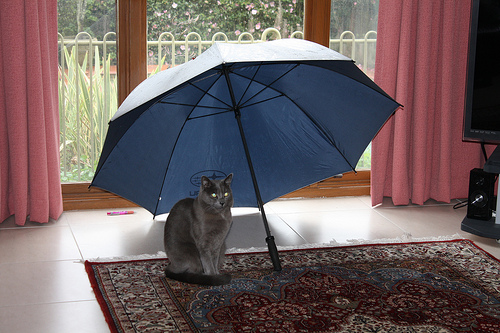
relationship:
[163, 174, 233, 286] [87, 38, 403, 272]
cat under umbrella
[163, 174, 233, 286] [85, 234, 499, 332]
cat on rug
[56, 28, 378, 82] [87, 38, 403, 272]
fence behind umbrella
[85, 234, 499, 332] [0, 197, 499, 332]
rug on floor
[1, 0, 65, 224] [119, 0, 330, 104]
curtains near door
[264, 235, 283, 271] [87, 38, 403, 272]
handle of umbrella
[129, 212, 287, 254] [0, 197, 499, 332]
shadow on floor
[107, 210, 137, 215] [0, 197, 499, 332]
marker on floor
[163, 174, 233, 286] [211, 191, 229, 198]
cat has eyes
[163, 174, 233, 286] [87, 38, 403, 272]
cat sitting under umbrella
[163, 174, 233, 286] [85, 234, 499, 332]
cat sitting on rug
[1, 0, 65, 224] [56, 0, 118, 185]
curtains by window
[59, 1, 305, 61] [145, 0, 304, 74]
bush outside window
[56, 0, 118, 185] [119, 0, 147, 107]
window by wood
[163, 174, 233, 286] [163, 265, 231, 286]
cat has tail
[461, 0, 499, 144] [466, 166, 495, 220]
television above speakers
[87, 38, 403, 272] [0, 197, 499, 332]
umbrella on floor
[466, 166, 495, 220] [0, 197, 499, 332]
speakers on floor